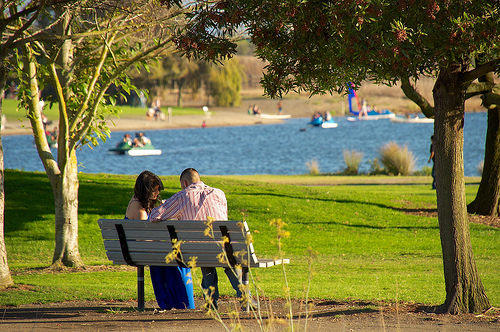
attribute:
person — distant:
[198, 106, 208, 128]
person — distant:
[274, 98, 284, 115]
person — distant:
[252, 103, 262, 117]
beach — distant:
[0, 97, 290, 131]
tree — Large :
[1, 0, 185, 275]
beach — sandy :
[5, 103, 290, 130]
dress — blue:
[127, 169, 195, 310]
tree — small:
[244, 11, 498, 318]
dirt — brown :
[365, 294, 471, 330]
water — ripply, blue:
[230, 136, 290, 151]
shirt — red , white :
[166, 184, 267, 234]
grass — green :
[291, 189, 404, 261]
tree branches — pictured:
[73, 7, 138, 80]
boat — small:
[106, 139, 162, 159]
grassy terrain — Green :
[294, 193, 389, 270]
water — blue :
[1, 105, 496, 181]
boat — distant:
[115, 146, 163, 156]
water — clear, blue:
[155, 129, 430, 148]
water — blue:
[2, 109, 498, 176]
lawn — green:
[0, 93, 498, 313]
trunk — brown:
[403, 79, 498, 304]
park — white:
[15, 21, 499, 286]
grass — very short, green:
[296, 197, 404, 268]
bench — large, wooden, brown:
[98, 219, 289, 311]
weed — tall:
[268, 213, 302, 329]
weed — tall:
[292, 242, 319, 330]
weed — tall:
[200, 215, 260, 330]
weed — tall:
[164, 239, 234, 330]